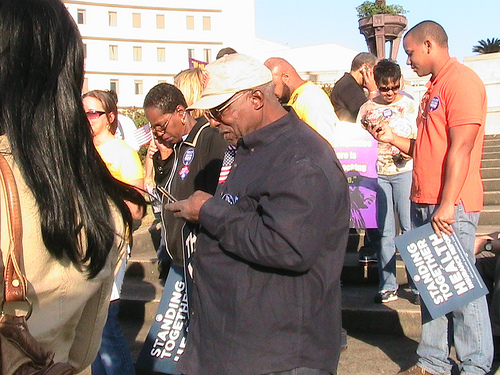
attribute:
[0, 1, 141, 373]
long haired woman — black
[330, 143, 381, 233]
poster — purple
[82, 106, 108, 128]
sunglasses — purple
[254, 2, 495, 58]
sky — blue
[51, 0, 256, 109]
building — tall, white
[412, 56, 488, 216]
shirt — orange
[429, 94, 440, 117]
button — blue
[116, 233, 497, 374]
floor — cement, concrete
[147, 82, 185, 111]
hair — black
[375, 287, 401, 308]
shoe — black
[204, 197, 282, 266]
sleeve — dark, long